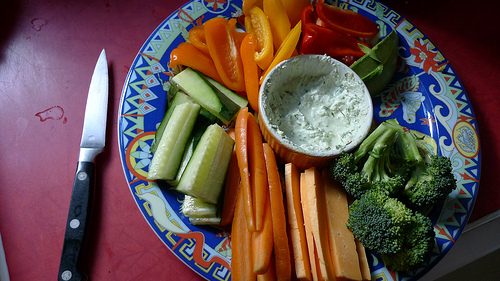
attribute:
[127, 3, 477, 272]
plate — blue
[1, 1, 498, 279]
table — red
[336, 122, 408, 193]
broccoli — green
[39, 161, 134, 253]
handle — black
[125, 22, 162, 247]
plate — multi-colored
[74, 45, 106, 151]
blade — silver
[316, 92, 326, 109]
dressing — white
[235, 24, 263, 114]
pepper — orange